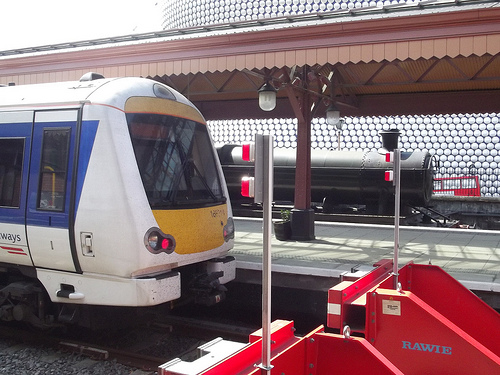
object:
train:
[0, 72, 236, 335]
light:
[146, 228, 164, 253]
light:
[222, 218, 236, 242]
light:
[153, 82, 176, 99]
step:
[55, 289, 85, 300]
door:
[25, 107, 82, 273]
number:
[209, 207, 226, 218]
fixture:
[257, 77, 280, 113]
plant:
[271, 207, 293, 241]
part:
[0, 283, 56, 331]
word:
[401, 340, 457, 354]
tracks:
[34, 315, 262, 370]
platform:
[235, 216, 500, 305]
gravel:
[0, 340, 157, 374]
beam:
[288, 70, 315, 240]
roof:
[0, 1, 499, 119]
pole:
[262, 133, 273, 374]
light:
[239, 177, 252, 199]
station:
[0, 22, 499, 372]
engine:
[218, 138, 445, 214]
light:
[242, 144, 251, 160]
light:
[325, 102, 341, 127]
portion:
[125, 97, 230, 257]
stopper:
[158, 258, 499, 374]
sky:
[1, 0, 160, 52]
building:
[153, 0, 430, 201]